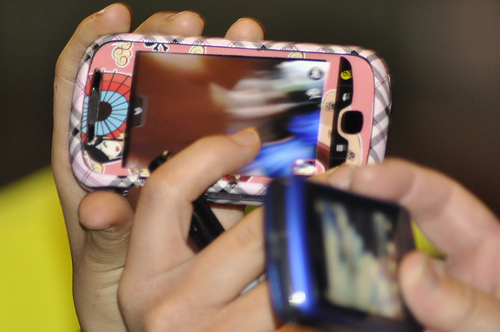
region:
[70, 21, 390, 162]
A colored cell phone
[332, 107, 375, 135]
A colored cell phone black button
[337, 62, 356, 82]
A colored cell phone yellow button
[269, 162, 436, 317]
A blue and black phone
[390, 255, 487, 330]
A small brown finger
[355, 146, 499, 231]
A small brown finger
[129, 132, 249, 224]
A small brown finger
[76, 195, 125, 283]
A small brown finger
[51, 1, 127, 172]
A small brown finger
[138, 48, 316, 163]
A coloured phone's sreen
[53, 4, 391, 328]
a person is holding a cell phone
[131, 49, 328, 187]
the screen of the cell phone is rectangular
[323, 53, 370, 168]
a control panel is at the bottom of the phone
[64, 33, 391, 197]
the phone has a plaid trim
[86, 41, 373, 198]
a colorful design surrounds the screen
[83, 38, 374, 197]
coral is the background of the design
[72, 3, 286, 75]
three fingers are holding the device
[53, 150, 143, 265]
a thumb is holding the device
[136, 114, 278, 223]
a finger is on the cell's screen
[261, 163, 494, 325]
a hand is holding a blue phone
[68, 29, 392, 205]
Pink and black telephone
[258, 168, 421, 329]
Black and blue camera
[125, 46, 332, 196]
Blury picture on phone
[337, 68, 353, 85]
Circular green led button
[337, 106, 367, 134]
Black square button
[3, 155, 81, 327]
Yellow object in the background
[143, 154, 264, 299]
Black and white object in hand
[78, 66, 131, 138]
Blue, orange, red and black picture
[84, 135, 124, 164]
Picture of a smiling girl on phone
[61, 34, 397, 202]
Long rectangular phone being held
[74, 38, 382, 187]
A colored mobile phone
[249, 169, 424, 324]
A blue and black mobile phone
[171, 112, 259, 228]
A brown finger holding a phone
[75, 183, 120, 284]
A brown finger holding a phone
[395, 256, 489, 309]
A brown finger holding a phone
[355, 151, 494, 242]
A brown finger holding a phone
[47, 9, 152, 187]
A brown finger holding a phone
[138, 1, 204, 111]
A brown finger holding a phone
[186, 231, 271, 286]
A brown finger holding a phone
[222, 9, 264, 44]
A brown finger holding a phone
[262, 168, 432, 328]
The indistinct image of a smart phone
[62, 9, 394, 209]
A hand holding a multicolored smart phone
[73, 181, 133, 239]
The tip of someone's thumb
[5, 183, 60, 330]
An indistinct patch of yellow background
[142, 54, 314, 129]
The screen of a smart phone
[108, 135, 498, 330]
A pair of hands holding a phone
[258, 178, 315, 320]
The blue and black edge of a smart phone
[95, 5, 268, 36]
Several fingers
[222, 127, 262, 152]
Somebody's fingernail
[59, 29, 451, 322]
A pair of smart phones held in someone's hands